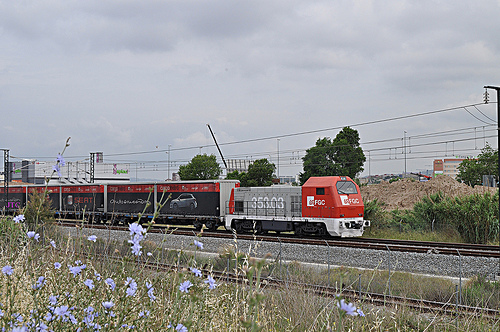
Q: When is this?
A: Daytime.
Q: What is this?
A: Train.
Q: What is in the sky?
A: Nothing.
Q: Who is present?
A: No one.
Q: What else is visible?
A: Trees.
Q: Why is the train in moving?
A: Travelling.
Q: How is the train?
A: In motion.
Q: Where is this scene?
A: Train yard.